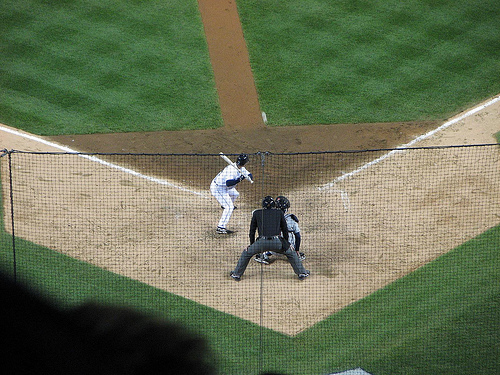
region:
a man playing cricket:
[204, 145, 254, 245]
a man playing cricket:
[221, 197, 309, 285]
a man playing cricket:
[254, 195, 311, 263]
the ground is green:
[1, 2, 477, 124]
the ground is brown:
[0, 95, 497, 335]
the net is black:
[0, 143, 499, 368]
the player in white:
[196, 140, 263, 238]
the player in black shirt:
[245, 202, 301, 242]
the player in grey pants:
[231, 237, 311, 289]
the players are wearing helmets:
[203, 144, 328, 286]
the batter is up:
[192, 131, 285, 256]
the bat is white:
[218, 134, 273, 209]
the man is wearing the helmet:
[220, 146, 255, 172]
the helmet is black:
[220, 144, 255, 172]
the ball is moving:
[207, 78, 307, 146]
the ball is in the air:
[243, 99, 298, 131]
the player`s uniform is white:
[204, 144, 282, 231]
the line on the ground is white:
[341, 95, 478, 199]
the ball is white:
[241, 85, 291, 136]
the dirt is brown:
[185, 5, 323, 144]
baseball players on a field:
[147, 137, 342, 298]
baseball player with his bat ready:
[174, 129, 276, 253]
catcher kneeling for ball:
[223, 194, 317, 281]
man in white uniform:
[184, 149, 266, 247]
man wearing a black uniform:
[220, 184, 322, 308]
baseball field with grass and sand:
[16, 9, 491, 346]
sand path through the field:
[17, 130, 354, 344]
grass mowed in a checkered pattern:
[23, 13, 208, 122]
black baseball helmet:
[217, 140, 264, 182]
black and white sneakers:
[207, 219, 242, 246]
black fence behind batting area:
[5, 140, 499, 373]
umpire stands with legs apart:
[227, 197, 316, 282]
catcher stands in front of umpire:
[256, 196, 309, 261]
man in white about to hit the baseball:
[206, 137, 254, 237]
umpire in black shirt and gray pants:
[232, 195, 307, 285]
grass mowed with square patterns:
[1, 0, 499, 199]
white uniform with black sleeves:
[208, 147, 254, 239]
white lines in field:
[4, 77, 496, 239]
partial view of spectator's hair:
[0, 258, 255, 373]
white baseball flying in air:
[256, 105, 271, 124]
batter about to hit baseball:
[207, 148, 253, 231]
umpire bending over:
[229, 197, 311, 279]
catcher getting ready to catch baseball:
[250, 194, 305, 261]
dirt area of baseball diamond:
[0, 95, 497, 337]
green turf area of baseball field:
[237, 3, 497, 123]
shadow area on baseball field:
[0, 255, 221, 369]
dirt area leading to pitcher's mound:
[193, 0, 265, 133]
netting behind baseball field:
[0, 144, 496, 374]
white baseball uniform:
[210, 165, 251, 231]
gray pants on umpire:
[232, 235, 308, 270]